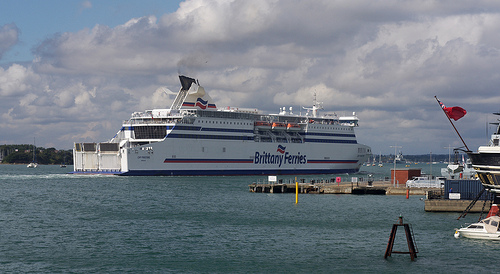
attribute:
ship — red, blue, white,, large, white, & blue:
[71, 75, 359, 174]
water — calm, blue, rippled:
[2, 162, 497, 272]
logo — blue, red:
[254, 143, 308, 166]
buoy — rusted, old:
[385, 217, 419, 260]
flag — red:
[439, 103, 466, 122]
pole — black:
[432, 94, 472, 155]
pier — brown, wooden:
[249, 181, 446, 195]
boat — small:
[57, 162, 67, 168]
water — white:
[1, 172, 116, 182]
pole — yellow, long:
[292, 178, 299, 205]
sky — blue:
[1, 1, 498, 155]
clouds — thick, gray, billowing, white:
[0, 1, 499, 155]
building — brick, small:
[387, 167, 423, 188]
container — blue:
[442, 178, 491, 199]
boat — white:
[453, 214, 499, 242]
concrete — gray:
[421, 198, 492, 211]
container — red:
[389, 167, 420, 182]